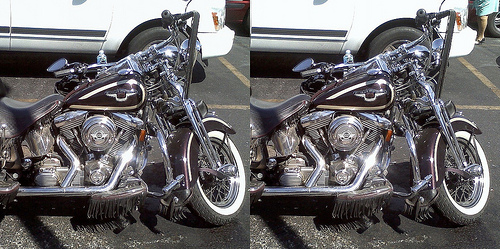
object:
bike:
[0, 9, 247, 226]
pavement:
[0, 32, 250, 248]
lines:
[206, 56, 250, 111]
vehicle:
[251, 0, 479, 60]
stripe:
[250, 26, 348, 37]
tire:
[368, 26, 434, 59]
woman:
[473, 0, 500, 45]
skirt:
[472, 0, 499, 17]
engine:
[33, 110, 146, 197]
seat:
[1, 93, 63, 138]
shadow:
[0, 197, 168, 249]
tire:
[189, 127, 248, 226]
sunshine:
[121, 149, 136, 163]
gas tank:
[60, 74, 149, 114]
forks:
[202, 153, 232, 199]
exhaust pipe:
[16, 134, 135, 197]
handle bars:
[47, 9, 189, 79]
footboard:
[90, 178, 147, 202]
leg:
[480, 14, 489, 43]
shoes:
[474, 37, 485, 46]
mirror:
[46, 57, 69, 72]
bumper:
[449, 26, 480, 58]